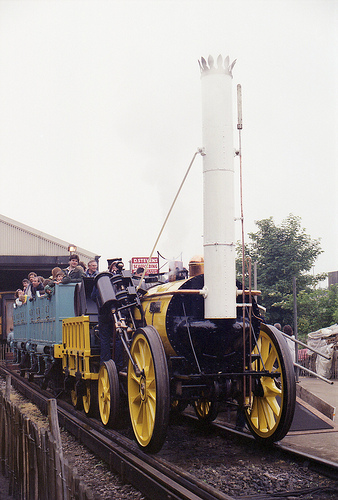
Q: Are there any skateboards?
A: No, there are no skateboards.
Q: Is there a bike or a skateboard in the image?
A: No, there are no skateboards or bikes.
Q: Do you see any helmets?
A: No, there are no helmets.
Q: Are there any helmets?
A: No, there are no helmets.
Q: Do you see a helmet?
A: No, there are no helmets.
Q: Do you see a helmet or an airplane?
A: No, there are no helmets or airplanes.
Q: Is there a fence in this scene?
A: Yes, there is a fence.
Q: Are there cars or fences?
A: Yes, there is a fence.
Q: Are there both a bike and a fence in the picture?
A: No, there is a fence but no bikes.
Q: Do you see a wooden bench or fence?
A: Yes, there is a wood fence.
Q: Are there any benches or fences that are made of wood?
A: Yes, the fence is made of wood.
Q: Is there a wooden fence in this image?
A: Yes, there is a wood fence.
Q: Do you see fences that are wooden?
A: Yes, there is a fence that is wooden.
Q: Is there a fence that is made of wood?
A: Yes, there is a fence that is made of wood.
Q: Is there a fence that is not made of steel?
A: Yes, there is a fence that is made of wood.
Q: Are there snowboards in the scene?
A: No, there are no snowboards.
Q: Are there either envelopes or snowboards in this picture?
A: No, there are no snowboards or envelopes.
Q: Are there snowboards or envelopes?
A: No, there are no snowboards or envelopes.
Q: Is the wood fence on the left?
A: Yes, the fence is on the left of the image.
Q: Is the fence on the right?
A: No, the fence is on the left of the image.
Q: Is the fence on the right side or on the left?
A: The fence is on the left of the image.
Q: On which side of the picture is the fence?
A: The fence is on the left of the image.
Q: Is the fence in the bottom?
A: Yes, the fence is in the bottom of the image.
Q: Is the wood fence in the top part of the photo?
A: No, the fence is in the bottom of the image.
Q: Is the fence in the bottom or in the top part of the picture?
A: The fence is in the bottom of the image.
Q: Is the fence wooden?
A: Yes, the fence is wooden.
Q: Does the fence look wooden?
A: Yes, the fence is wooden.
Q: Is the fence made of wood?
A: Yes, the fence is made of wood.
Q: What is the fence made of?
A: The fence is made of wood.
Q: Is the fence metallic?
A: No, the fence is wooden.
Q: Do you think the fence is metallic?
A: No, the fence is wooden.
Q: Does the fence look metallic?
A: No, the fence is wooden.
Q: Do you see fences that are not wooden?
A: No, there is a fence but it is wooden.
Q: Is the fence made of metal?
A: No, the fence is made of wood.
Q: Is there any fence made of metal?
A: No, there is a fence but it is made of wood.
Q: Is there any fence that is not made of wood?
A: No, there is a fence but it is made of wood.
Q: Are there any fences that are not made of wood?
A: No, there is a fence but it is made of wood.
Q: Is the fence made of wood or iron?
A: The fence is made of wood.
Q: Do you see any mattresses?
A: No, there are no mattresses.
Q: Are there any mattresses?
A: No, there are no mattresses.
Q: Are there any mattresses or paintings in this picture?
A: No, there are no mattresses or paintings.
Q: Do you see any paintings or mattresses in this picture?
A: No, there are no mattresses or paintings.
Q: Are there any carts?
A: No, there are no carts.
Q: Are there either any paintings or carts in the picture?
A: No, there are no carts or paintings.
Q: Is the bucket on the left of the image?
A: Yes, the bucket is on the left of the image.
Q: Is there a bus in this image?
A: No, there are no buses.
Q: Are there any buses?
A: No, there are no buses.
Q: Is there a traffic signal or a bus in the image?
A: No, there are no buses or traffic lights.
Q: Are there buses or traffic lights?
A: No, there are no buses or traffic lights.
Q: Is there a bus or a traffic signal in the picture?
A: No, there are no buses or traffic lights.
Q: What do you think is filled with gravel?
A: The railroad tracks are filled with gravel.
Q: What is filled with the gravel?
A: The railroad tracks are filled with gravel.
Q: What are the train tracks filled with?
A: The train tracks are filled with gravel.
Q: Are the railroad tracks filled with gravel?
A: Yes, the railroad tracks are filled with gravel.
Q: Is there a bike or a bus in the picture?
A: No, there are no buses or bikes.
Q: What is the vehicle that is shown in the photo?
A: The vehicle is a car.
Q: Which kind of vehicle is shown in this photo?
A: The vehicle is a car.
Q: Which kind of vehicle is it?
A: The vehicle is a car.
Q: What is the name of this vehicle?
A: This is a car.